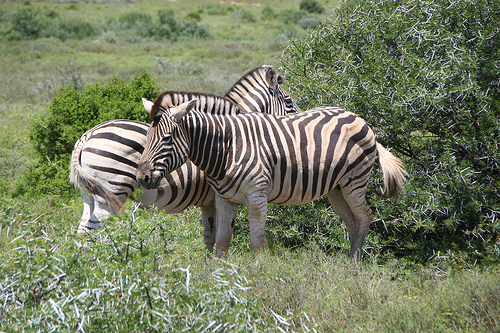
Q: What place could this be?
A: It is a plain.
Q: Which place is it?
A: It is a plain.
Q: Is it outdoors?
A: Yes, it is outdoors.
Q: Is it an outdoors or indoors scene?
A: It is outdoors.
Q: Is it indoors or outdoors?
A: It is outdoors.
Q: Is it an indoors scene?
A: No, it is outdoors.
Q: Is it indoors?
A: No, it is outdoors.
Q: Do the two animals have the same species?
A: Yes, all the animals are zebras.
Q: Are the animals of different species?
A: No, all the animals are zebras.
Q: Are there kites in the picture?
A: No, there are no kites.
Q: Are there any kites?
A: No, there are no kites.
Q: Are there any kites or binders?
A: No, there are no kites or binders.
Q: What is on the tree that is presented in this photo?
A: The leaves are on the tree.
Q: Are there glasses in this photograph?
A: No, there are no glasses.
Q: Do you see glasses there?
A: No, there are no glasses.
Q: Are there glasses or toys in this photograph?
A: No, there are no glasses or toys.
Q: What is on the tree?
A: The leaves are on the tree.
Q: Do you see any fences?
A: No, there are no fences.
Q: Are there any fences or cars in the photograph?
A: No, there are no fences or cars.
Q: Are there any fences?
A: No, there are no fences.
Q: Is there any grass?
A: Yes, there is grass.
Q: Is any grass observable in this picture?
A: Yes, there is grass.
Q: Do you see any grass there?
A: Yes, there is grass.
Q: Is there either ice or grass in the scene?
A: Yes, there is grass.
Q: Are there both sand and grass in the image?
A: No, there is grass but no sand.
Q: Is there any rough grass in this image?
A: Yes, there is rough grass.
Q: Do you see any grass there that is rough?
A: Yes, there is grass that is rough.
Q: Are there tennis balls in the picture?
A: No, there are no tennis balls.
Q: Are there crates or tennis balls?
A: No, there are no tennis balls or crates.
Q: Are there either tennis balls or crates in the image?
A: No, there are no tennis balls or crates.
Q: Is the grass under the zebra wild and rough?
A: Yes, the grass is wild and rough.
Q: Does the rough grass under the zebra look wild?
A: Yes, the grass is wild.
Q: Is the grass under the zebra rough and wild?
A: Yes, the grass is rough and wild.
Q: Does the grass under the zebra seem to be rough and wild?
A: Yes, the grass is rough and wild.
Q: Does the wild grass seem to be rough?
A: Yes, the grass is rough.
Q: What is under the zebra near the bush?
A: The grass is under the zebra.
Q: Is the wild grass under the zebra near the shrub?
A: Yes, the grass is under the zebra.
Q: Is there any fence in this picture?
A: No, there are no fences.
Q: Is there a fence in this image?
A: No, there are no fences.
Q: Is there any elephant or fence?
A: No, there are no fences or elephants.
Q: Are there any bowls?
A: No, there are no bowls.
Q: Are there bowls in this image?
A: No, there are no bowls.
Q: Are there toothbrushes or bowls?
A: No, there are no bowls or toothbrushes.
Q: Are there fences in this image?
A: No, there are no fences.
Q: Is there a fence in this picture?
A: No, there are no fences.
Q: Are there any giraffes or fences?
A: No, there are no fences or giraffes.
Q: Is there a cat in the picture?
A: No, there are no cats.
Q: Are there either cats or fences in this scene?
A: No, there are no cats or fences.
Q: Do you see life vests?
A: No, there are no life vests.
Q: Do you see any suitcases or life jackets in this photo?
A: No, there are no life jackets or suitcases.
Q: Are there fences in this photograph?
A: No, there are no fences.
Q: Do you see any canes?
A: No, there are no canes.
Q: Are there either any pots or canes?
A: No, there are no canes or pots.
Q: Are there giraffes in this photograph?
A: No, there are no giraffes.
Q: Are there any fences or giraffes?
A: No, there are no giraffes or fences.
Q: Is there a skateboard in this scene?
A: No, there are no skateboards.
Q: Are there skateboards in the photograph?
A: No, there are no skateboards.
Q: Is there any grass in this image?
A: Yes, there is grass.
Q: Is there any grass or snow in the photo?
A: Yes, there is grass.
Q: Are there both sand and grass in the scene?
A: No, there is grass but no sand.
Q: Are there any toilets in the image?
A: No, there are no toilets.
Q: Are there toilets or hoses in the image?
A: No, there are no toilets or hoses.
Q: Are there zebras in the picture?
A: Yes, there is a zebra.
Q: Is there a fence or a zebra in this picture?
A: Yes, there is a zebra.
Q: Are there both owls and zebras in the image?
A: No, there is a zebra but no owls.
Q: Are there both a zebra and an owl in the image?
A: No, there is a zebra but no owls.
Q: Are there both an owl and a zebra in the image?
A: No, there is a zebra but no owls.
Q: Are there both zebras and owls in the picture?
A: No, there is a zebra but no owls.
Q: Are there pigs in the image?
A: No, there are no pigs.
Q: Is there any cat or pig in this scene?
A: No, there are no pigs or cats.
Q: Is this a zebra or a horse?
A: This is a zebra.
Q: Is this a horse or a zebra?
A: This is a zebra.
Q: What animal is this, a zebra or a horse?
A: This is a zebra.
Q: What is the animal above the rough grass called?
A: The animal is a zebra.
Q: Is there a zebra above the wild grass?
A: Yes, there is a zebra above the grass.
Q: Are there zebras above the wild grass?
A: Yes, there is a zebra above the grass.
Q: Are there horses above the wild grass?
A: No, there is a zebra above the grass.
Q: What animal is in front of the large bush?
A: The zebra is in front of the bush.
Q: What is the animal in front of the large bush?
A: The animal is a zebra.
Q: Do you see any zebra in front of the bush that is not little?
A: Yes, there is a zebra in front of the shrub.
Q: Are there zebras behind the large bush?
A: No, the zebra is in front of the shrub.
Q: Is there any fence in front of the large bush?
A: No, there is a zebra in front of the shrub.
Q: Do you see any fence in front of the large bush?
A: No, there is a zebra in front of the shrub.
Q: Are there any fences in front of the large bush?
A: No, there is a zebra in front of the shrub.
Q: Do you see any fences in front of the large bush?
A: No, there is a zebra in front of the shrub.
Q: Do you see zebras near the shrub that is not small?
A: Yes, there is a zebra near the shrub.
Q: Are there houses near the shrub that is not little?
A: No, there is a zebra near the shrub.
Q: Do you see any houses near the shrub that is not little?
A: No, there is a zebra near the shrub.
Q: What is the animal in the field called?
A: The animal is a zebra.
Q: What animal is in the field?
A: The animal is a zebra.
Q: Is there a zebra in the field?
A: Yes, there is a zebra in the field.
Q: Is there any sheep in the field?
A: No, there is a zebra in the field.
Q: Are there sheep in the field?
A: No, there is a zebra in the field.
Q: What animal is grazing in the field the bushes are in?
A: The zebra is grazing in the field.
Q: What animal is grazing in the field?
A: The zebra is grazing in the field.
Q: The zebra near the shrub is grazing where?
A: The zebra is grazing in the field.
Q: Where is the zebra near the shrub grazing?
A: The zebra is grazing in the field.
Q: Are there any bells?
A: No, there are no bells.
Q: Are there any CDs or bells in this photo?
A: No, there are no bells or cds.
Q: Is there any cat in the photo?
A: No, there are no cats.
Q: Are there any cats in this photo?
A: No, there are no cats.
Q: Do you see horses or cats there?
A: No, there are no cats or horses.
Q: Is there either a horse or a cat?
A: No, there are no cats or horses.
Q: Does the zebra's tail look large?
A: Yes, the tail is large.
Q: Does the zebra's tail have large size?
A: Yes, the tail is large.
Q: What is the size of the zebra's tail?
A: The tail is large.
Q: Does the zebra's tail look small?
A: No, the tail is large.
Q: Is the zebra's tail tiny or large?
A: The tail is large.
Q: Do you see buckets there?
A: No, there are no buckets.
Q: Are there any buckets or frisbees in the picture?
A: No, there are no buckets or frisbees.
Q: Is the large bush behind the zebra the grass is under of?
A: Yes, the shrub is behind the zebra.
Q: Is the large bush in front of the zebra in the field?
A: No, the bush is behind the zebra.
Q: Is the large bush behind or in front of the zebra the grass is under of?
A: The bush is behind the zebra.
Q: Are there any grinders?
A: No, there are no grinders.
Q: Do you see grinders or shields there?
A: No, there are no grinders or shields.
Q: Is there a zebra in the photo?
A: Yes, there is a zebra.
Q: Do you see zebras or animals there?
A: Yes, there is a zebra.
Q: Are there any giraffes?
A: No, there are no giraffes.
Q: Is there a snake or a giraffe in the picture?
A: No, there are no giraffes or snakes.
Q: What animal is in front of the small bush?
A: The animal is a zebra.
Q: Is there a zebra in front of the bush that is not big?
A: Yes, there is a zebra in front of the shrub.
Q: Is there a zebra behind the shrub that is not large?
A: No, the zebra is in front of the bush.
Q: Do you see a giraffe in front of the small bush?
A: No, there is a zebra in front of the bush.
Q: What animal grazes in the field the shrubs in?
A: The zebra grazes in the field.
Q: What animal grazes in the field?
A: The zebra grazes in the field.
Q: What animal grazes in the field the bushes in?
A: The animal is a zebra.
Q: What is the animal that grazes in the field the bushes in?
A: The animal is a zebra.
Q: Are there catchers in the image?
A: No, there are no catchers.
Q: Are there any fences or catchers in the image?
A: No, there are no catchers or fences.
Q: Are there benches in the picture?
A: No, there are no benches.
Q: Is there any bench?
A: No, there are no benches.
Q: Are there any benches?
A: No, there are no benches.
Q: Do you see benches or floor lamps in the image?
A: No, there are no benches or floor lamps.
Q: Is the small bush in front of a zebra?
A: No, the bush is behind a zebra.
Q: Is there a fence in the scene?
A: No, there are no fences.